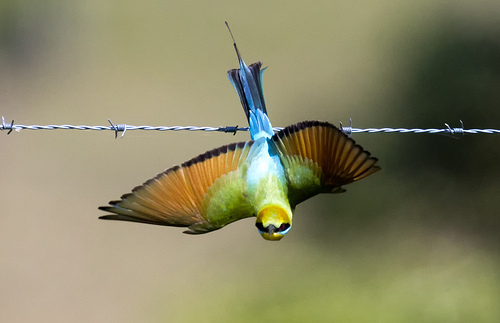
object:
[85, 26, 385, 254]
bird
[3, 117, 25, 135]
barbs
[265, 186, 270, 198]
feathers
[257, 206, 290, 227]
semi-circle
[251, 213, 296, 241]
head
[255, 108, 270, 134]
feathers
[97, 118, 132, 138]
barbs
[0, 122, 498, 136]
barbed wire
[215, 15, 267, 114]
tail feathers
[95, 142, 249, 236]
feathers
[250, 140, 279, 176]
bird breast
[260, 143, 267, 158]
feathers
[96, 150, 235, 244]
wing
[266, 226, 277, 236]
beak